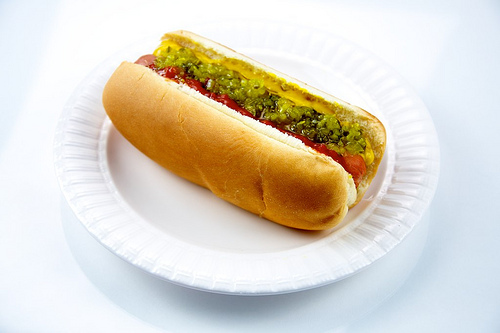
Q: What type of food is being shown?
A: Hot dog.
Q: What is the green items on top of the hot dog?
A: Relish.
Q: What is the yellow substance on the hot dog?
A: Mustard.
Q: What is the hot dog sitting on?
A: Plate.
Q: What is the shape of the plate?
A: Round.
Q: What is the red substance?
A: Ketchup.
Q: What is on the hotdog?
A: Relish.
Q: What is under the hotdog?
A: Bun.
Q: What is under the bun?
A: Plate.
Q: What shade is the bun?
A: Tan.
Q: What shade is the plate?
A: White.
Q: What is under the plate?
A: Table.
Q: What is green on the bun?
A: Relish.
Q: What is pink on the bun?
A: Hotdog.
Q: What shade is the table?
A: Light blue.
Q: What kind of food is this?
A: Hot dog.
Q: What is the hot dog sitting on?
A: A white plate.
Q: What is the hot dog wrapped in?
A: A hotdog bun.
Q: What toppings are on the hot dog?
A: Mustard,ketchup, and relish.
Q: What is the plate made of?
A: Paper.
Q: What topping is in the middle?
A: Relish.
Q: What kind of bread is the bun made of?
A: White bread.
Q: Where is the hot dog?
A: On the plate.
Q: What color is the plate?
A: White.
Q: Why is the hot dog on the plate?
A: Ready to be a meal.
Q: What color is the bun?
A: Brown.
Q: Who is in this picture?
A: No one.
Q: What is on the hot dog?
A: Mustard.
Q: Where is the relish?
A: On the hot dog.